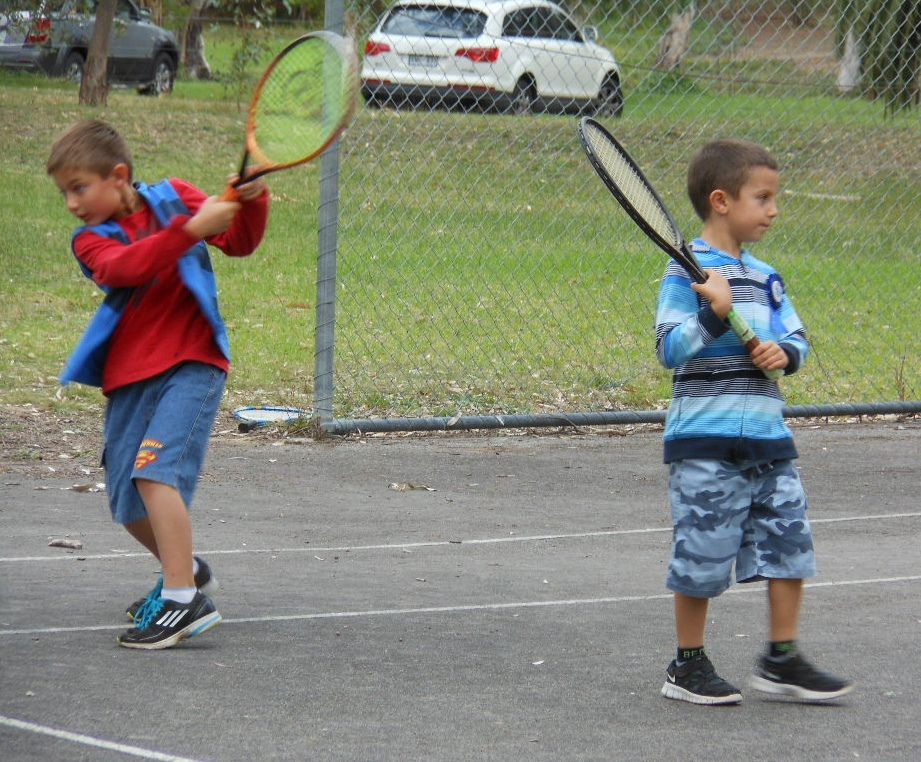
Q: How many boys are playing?
A: Two.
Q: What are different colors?
A: The cars.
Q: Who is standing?
A: The two boys.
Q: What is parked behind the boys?
A: Two SUVs.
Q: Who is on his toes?
A: The boy in the red shirt.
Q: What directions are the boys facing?
A: Opposite.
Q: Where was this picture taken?
A: On court.